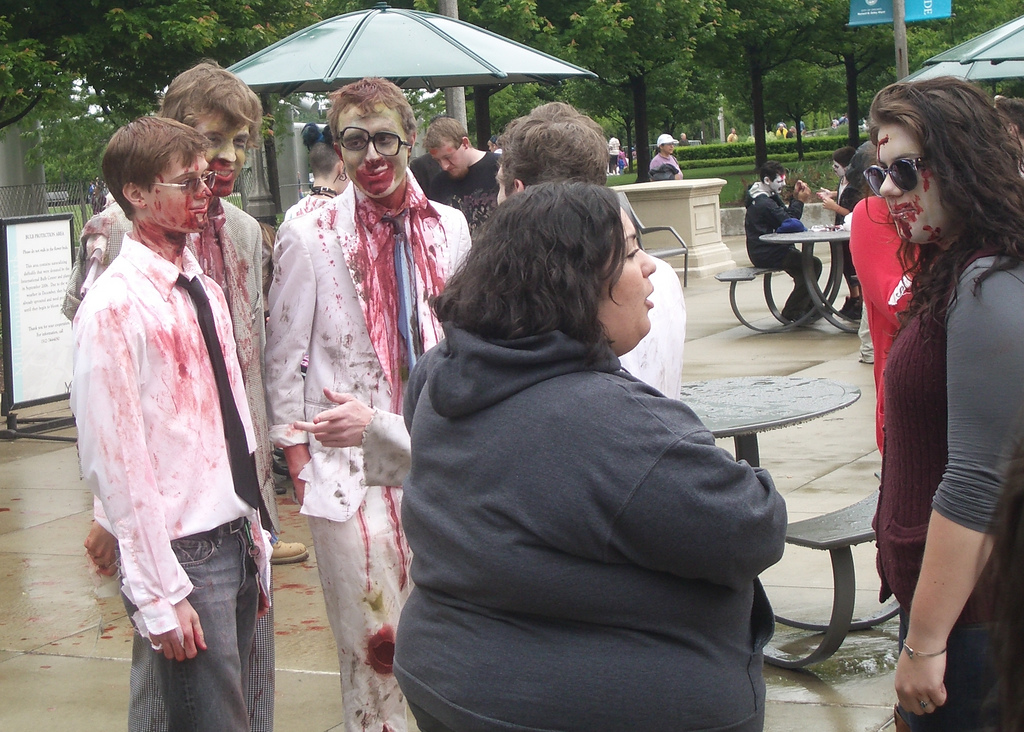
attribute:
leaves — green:
[603, 20, 693, 153]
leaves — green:
[691, 27, 769, 170]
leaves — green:
[590, 8, 677, 198]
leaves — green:
[150, 3, 239, 76]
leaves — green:
[590, 8, 774, 158]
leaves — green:
[539, 25, 644, 123]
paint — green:
[289, 97, 479, 266]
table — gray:
[713, 387, 935, 650]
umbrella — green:
[262, 27, 507, 94]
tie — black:
[107, 273, 221, 507]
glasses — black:
[303, 85, 417, 196]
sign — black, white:
[17, 223, 101, 421]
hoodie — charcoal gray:
[417, 203, 709, 653]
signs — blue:
[845, 6, 964, 46]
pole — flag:
[845, 47, 964, 99]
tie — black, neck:
[151, 258, 276, 486]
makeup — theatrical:
[292, 83, 420, 220]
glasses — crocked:
[292, 83, 420, 220]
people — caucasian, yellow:
[657, 106, 806, 161]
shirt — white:
[72, 138, 294, 632]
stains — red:
[72, 138, 294, 632]